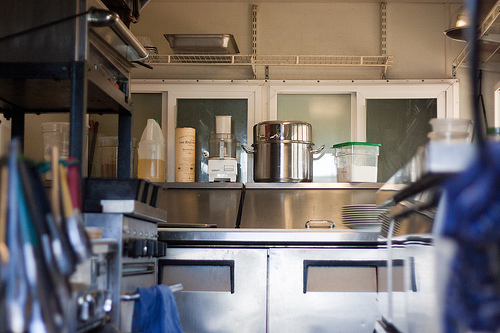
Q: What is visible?
A: The container.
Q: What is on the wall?
A: Rack.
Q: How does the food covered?
A: Lid.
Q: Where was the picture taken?
A: In a kitchen.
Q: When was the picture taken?
A: Daytime.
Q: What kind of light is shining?
A: Sunlight.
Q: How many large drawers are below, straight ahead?
A: Two.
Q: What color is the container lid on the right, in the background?
A: Green.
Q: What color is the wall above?
A: White.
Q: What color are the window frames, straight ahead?
A: White.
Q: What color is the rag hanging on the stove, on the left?
A: Blue.